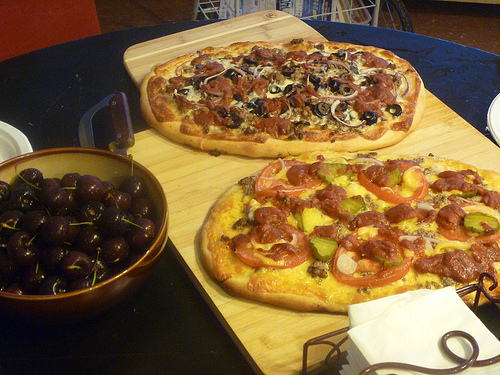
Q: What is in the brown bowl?
A: Cherries.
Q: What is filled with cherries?
A: Bowl.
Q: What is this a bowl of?
A: Cherries on their stems.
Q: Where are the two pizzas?
A: On wooden boards.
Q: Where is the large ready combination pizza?
A: On cutting board.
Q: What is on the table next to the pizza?
A: Brown bowl of cherries.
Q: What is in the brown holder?
A: Large stack of white napkins.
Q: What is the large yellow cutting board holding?
A: Two pizzas.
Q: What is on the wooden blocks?
A: Pizza.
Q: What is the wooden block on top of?
A: Table.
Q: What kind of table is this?
A: Black round table.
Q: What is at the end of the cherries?
A: Green stem.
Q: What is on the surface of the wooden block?
A: Striation marks.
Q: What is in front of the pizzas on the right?
A: Napkins.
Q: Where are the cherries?
A: Bowl.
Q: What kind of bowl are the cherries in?
A: Round brown bowl.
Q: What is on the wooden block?
A: Pizza.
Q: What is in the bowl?
A: Cherries.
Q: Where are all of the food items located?
A: On table.